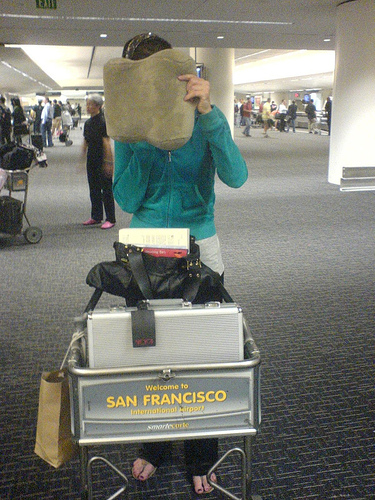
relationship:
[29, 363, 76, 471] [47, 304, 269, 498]
brown bag hanging from cart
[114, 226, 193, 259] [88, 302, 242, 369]
book in carry case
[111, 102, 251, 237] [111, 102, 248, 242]
fabric on fabric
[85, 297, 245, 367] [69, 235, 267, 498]
briefcase in cart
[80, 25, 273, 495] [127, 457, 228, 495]
woman wearing sandals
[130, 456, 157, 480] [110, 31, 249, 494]
foot of woman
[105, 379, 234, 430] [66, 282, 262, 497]
text on cart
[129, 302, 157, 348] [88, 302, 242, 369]
tag on carry case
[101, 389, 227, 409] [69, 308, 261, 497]
san francisco on cart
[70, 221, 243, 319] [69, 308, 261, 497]
bag on cart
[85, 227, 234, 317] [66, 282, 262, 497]
bag on cart